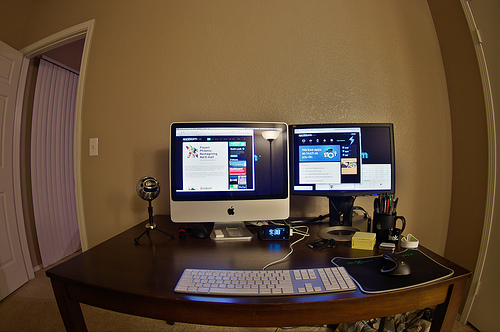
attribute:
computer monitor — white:
[165, 115, 293, 244]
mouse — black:
[370, 245, 414, 276]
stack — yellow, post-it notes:
[351, 227, 374, 252]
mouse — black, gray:
[357, 249, 444, 289]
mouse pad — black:
[323, 247, 459, 328]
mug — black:
[369, 194, 406, 236]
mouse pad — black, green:
[322, 242, 457, 295]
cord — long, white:
[265, 220, 311, 267]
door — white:
[27, 57, 79, 272]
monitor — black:
[287, 121, 396, 197]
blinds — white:
[22, 50, 87, 270]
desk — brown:
[46, 214, 473, 330]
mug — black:
[370, 209, 407, 236]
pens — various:
[372, 189, 399, 214]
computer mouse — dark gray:
[360, 235, 427, 283]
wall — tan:
[4, 2, 451, 255]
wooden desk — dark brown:
[47, 209, 242, 311]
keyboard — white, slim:
[172, 265, 357, 296]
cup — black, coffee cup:
[350, 211, 425, 270]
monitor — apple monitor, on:
[173, 113, 447, 250]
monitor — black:
[293, 120, 395, 194]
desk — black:
[43, 204, 478, 329]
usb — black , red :
[271, 228, 286, 236]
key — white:
[296, 285, 303, 291]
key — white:
[316, 285, 323, 293]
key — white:
[292, 272, 302, 279]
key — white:
[303, 282, 313, 287]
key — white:
[271, 281, 292, 293]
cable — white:
[259, 222, 310, 271]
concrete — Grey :
[104, 202, 396, 318]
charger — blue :
[253, 215, 310, 257]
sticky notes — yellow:
[348, 225, 383, 258]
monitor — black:
[287, 120, 397, 226]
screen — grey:
[166, 120, 289, 221]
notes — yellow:
[350, 229, 377, 253]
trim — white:
[330, 245, 456, 296]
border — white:
[329, 247, 457, 295]